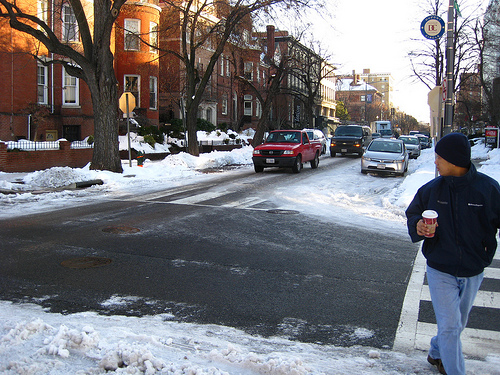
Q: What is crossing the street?
A: The man.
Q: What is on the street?
A: The crosswalk.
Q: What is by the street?
A: The piles of snow.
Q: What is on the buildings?
A: The sunlight.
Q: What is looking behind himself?
A: The man.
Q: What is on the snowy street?
A: The man.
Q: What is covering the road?
A: Snow.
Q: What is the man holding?
A: Red cup.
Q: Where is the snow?
A: In the road.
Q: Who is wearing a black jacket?
A: The man.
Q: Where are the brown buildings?
A: On the side of the road.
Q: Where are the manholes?
A: In the road.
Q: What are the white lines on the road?
A: Cross path.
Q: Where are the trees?
A: On the sidewalk.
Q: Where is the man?
A: In the crosswalk.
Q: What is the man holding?
A: Coffee cup.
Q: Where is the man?
A: Crosswalk.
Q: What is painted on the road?
A: Crosswalk.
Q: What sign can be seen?
A: Stop.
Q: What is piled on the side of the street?
A: Snow.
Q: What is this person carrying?
A: Cup of coffee.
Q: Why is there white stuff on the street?
A: It snowed.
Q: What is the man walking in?
A: The crosswalk.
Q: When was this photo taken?
A: During the daytime.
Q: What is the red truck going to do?
A: Stop at the stop sign.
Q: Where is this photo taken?
A: At an intersection.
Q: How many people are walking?
A: One.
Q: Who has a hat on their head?
A: The guy with coffee.